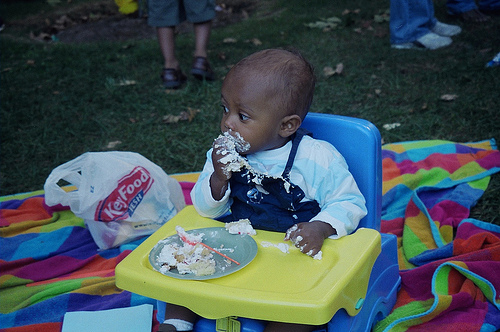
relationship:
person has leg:
[145, 1, 217, 88] [146, 1, 186, 87]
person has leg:
[145, 1, 217, 88] [184, 2, 217, 80]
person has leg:
[388, 1, 461, 51] [390, 3, 451, 50]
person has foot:
[145, 1, 217, 88] [159, 62, 187, 88]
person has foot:
[145, 1, 217, 88] [186, 55, 216, 80]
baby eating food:
[190, 45, 369, 257] [156, 227, 218, 277]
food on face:
[218, 131, 252, 174] [219, 69, 277, 155]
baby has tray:
[190, 45, 369, 257] [114, 204, 381, 327]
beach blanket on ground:
[1, 135, 499, 327] [1, 2, 498, 331]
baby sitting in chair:
[190, 45, 369, 257] [156, 113, 400, 331]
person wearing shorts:
[145, 1, 217, 88] [148, 1, 214, 28]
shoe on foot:
[162, 69, 187, 85] [159, 62, 187, 88]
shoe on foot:
[189, 58, 211, 76] [186, 55, 216, 80]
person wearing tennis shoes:
[388, 1, 461, 51] [389, 18, 464, 48]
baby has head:
[190, 45, 369, 257] [219, 47, 316, 154]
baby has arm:
[190, 45, 369, 257] [288, 139, 367, 261]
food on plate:
[156, 227, 218, 277] [148, 225, 259, 281]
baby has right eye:
[190, 45, 369, 257] [219, 104, 229, 114]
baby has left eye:
[190, 45, 369, 257] [238, 111, 249, 121]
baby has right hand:
[190, 45, 369, 257] [209, 137, 244, 179]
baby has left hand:
[190, 45, 369, 257] [284, 220, 331, 262]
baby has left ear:
[190, 45, 369, 257] [277, 114, 303, 138]